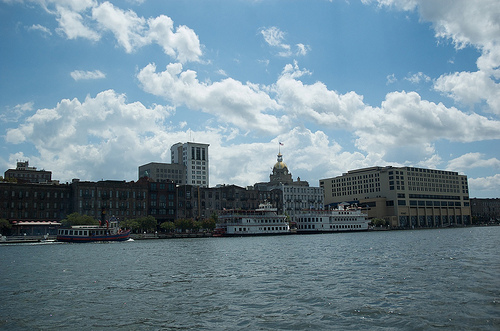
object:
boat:
[53, 220, 133, 244]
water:
[0, 225, 499, 331]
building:
[0, 177, 105, 237]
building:
[66, 178, 146, 230]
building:
[132, 173, 178, 234]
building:
[168, 140, 209, 189]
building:
[317, 165, 472, 231]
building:
[252, 139, 324, 231]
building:
[135, 162, 181, 188]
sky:
[0, 0, 498, 200]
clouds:
[66, 68, 107, 83]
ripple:
[0, 224, 499, 331]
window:
[81, 230, 89, 237]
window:
[62, 229, 67, 236]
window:
[75, 230, 81, 236]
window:
[93, 229, 101, 236]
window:
[97, 228, 105, 238]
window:
[109, 221, 115, 227]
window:
[112, 222, 118, 228]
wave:
[0, 226, 498, 330]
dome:
[270, 138, 289, 176]